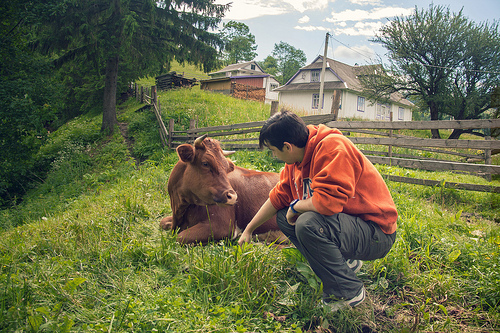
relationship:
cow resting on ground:
[157, 135, 292, 250] [8, 87, 499, 324]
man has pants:
[233, 105, 401, 308] [273, 202, 398, 303]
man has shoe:
[233, 105, 401, 308] [317, 283, 368, 312]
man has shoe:
[233, 105, 401, 308] [339, 256, 366, 273]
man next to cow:
[233, 105, 401, 308] [157, 135, 292, 250]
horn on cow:
[194, 132, 211, 149] [157, 135, 292, 250]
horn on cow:
[221, 151, 238, 158] [157, 135, 292, 250]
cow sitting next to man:
[157, 135, 292, 250] [233, 105, 401, 308]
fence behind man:
[124, 80, 499, 196] [233, 105, 401, 308]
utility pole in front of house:
[313, 30, 332, 118] [275, 55, 418, 127]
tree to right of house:
[351, 5, 498, 151] [275, 55, 418, 127]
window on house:
[308, 91, 326, 112] [275, 55, 418, 127]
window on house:
[353, 96, 368, 113] [275, 55, 418, 127]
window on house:
[308, 69, 320, 81] [275, 55, 418, 127]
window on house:
[396, 106, 406, 122] [275, 55, 418, 127]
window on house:
[250, 65, 256, 71] [205, 58, 280, 104]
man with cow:
[233, 105, 401, 308] [157, 135, 292, 250]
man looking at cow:
[233, 105, 401, 308] [157, 135, 292, 250]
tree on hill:
[14, 4, 244, 153] [44, 82, 272, 213]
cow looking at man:
[157, 135, 292, 250] [233, 105, 401, 308]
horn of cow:
[194, 132, 211, 149] [157, 135, 292, 250]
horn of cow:
[221, 151, 238, 158] [157, 135, 292, 250]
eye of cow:
[201, 159, 210, 168] [157, 135, 292, 250]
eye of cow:
[227, 165, 233, 173] [157, 135, 292, 250]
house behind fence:
[275, 55, 418, 127] [124, 80, 499, 196]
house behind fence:
[205, 58, 280, 104] [124, 80, 499, 196]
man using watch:
[233, 105, 401, 308] [287, 196, 302, 216]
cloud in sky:
[326, 8, 421, 23] [155, 0, 499, 96]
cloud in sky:
[171, 1, 330, 20] [155, 0, 499, 96]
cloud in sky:
[298, 14, 311, 28] [155, 0, 499, 96]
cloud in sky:
[291, 24, 330, 34] [155, 0, 499, 96]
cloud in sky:
[333, 42, 379, 58] [155, 0, 499, 96]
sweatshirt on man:
[260, 121, 403, 236] [233, 105, 401, 308]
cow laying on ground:
[157, 135, 292, 250] [8, 87, 499, 324]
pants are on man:
[273, 202, 398, 303] [233, 105, 401, 308]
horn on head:
[194, 132, 211, 149] [172, 132, 243, 203]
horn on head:
[221, 151, 238, 158] [172, 132, 243, 203]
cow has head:
[157, 135, 292, 250] [172, 132, 243, 203]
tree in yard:
[351, 5, 498, 151] [140, 71, 498, 188]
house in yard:
[275, 55, 418, 127] [140, 71, 498, 188]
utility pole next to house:
[313, 30, 332, 118] [275, 55, 418, 127]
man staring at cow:
[233, 105, 401, 308] [157, 135, 292, 250]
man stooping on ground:
[233, 105, 401, 308] [8, 87, 499, 324]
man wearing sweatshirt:
[233, 105, 401, 308] [260, 121, 403, 236]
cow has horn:
[157, 135, 292, 250] [194, 132, 211, 149]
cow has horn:
[157, 135, 292, 250] [221, 151, 238, 158]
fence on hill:
[124, 80, 499, 196] [44, 82, 272, 213]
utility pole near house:
[313, 30, 332, 118] [275, 55, 418, 127]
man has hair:
[233, 105, 401, 308] [258, 108, 310, 149]